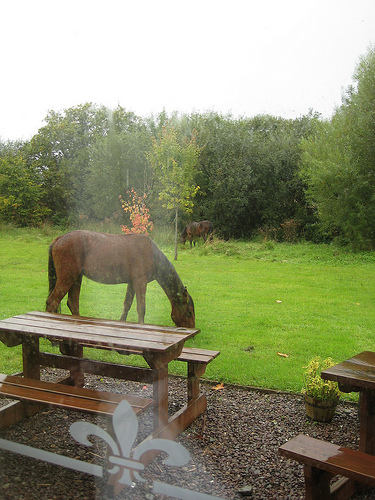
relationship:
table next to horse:
[1, 311, 220, 499] [45, 230, 196, 349]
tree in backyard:
[147, 124, 196, 263] [0, 217, 373, 498]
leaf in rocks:
[209, 378, 228, 391] [0, 365, 360, 498]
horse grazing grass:
[45, 230, 196, 349] [156, 247, 338, 362]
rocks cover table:
[42, 424, 236, 475] [2, 293, 233, 464]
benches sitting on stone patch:
[3, 307, 374, 498] [2, 357, 374, 497]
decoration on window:
[62, 388, 201, 492] [0, 4, 373, 497]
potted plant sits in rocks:
[301, 355, 340, 419] [236, 420, 253, 438]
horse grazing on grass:
[45, 230, 196, 349] [3, 223, 373, 401]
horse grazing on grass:
[177, 219, 213, 248] [3, 223, 373, 401]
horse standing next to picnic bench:
[10, 180, 225, 392] [0, 308, 216, 479]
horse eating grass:
[45, 230, 196, 349] [3, 223, 373, 401]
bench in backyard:
[282, 347, 370, 496] [0, 217, 373, 498]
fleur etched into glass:
[68, 398, 192, 485] [1, 6, 371, 498]